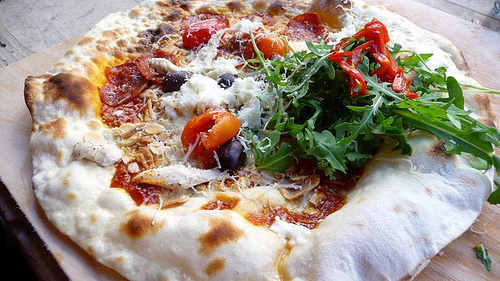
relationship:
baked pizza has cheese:
[23, 0, 500, 281] [143, 15, 358, 233]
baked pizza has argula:
[23, 0, 500, 281] [265, 72, 353, 148]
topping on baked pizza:
[286, 175, 316, 202] [23, 0, 500, 281]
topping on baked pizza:
[250, 19, 460, 180] [23, 0, 500, 281]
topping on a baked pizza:
[244, 32, 290, 61] [23, 0, 500, 281]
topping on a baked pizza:
[102, 64, 144, 104] [23, 0, 500, 281]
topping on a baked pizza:
[148, 57, 195, 92] [23, 0, 500, 281]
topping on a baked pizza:
[139, 54, 166, 82] [23, 0, 500, 281]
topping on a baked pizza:
[188, 107, 237, 154] [23, 0, 500, 281]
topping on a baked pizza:
[217, 140, 244, 172] [23, 0, 500, 281]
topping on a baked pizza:
[244, 26, 323, 86] [23, 0, 500, 281]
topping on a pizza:
[250, 19, 460, 180] [23, 9, 396, 272]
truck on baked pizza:
[190, 27, 445, 192] [23, 0, 500, 281]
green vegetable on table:
[250, 34, 472, 190] [437, 247, 490, 280]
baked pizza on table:
[23, 0, 500, 281] [5, 9, 488, 278]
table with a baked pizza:
[5, 9, 488, 278] [21, 0, 496, 280]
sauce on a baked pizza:
[315, 185, 340, 212] [23, 0, 500, 281]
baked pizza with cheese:
[23, 0, 500, 281] [161, 66, 266, 128]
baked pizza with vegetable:
[23, 0, 500, 281] [248, 17, 498, 204]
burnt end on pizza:
[17, 61, 117, 121] [56, 24, 449, 264]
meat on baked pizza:
[97, 55, 149, 108] [23, 0, 500, 281]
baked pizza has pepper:
[23, 0, 500, 281] [363, 12, 395, 74]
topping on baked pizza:
[181, 109, 241, 170] [23, 0, 500, 281]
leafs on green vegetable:
[357, 91, 444, 134] [238, 21, 500, 206]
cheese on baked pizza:
[70, 19, 340, 199] [23, 0, 500, 281]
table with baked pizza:
[0, 0, 499, 281] [23, 0, 500, 281]